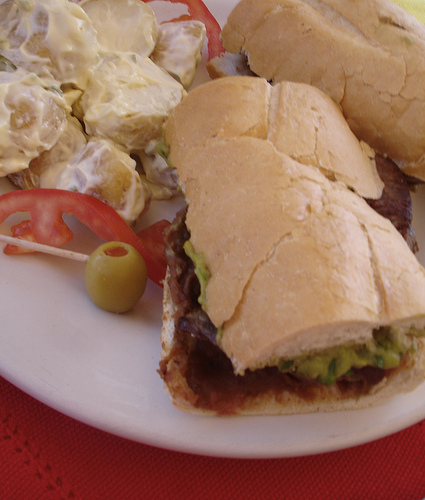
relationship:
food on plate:
[204, 0, 425, 184] [1, 2, 422, 457]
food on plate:
[158, 75, 423, 415] [1, 2, 422, 457]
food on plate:
[82, 238, 148, 315] [1, 2, 422, 457]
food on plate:
[0, 186, 171, 287] [1, 2, 422, 457]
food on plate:
[144, 0, 224, 63] [1, 2, 422, 457]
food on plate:
[0, 63, 73, 181] [3, 188, 421, 462]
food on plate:
[1, 68, 63, 176] [1, 2, 422, 457]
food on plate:
[0, 63, 73, 181] [1, 2, 422, 457]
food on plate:
[155, 74, 425, 420] [1, 274, 424, 464]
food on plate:
[82, 238, 148, 315] [1, 323, 153, 479]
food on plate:
[82, 238, 148, 315] [21, 171, 291, 342]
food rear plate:
[82, 238, 148, 315] [26, 322, 136, 436]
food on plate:
[0, 184, 172, 286] [0, 300, 163, 411]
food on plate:
[0, 184, 172, 286] [0, 256, 174, 414]